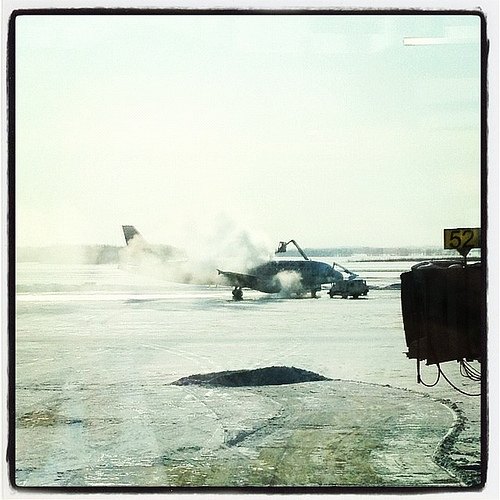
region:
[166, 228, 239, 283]
White smoke coming out of airplane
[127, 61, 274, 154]
Clear sunny blue day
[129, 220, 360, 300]
Airplane with white smoke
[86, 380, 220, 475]
Skid marks on pathway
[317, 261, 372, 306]
Truck close to airplane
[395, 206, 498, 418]
Equipment with 52 listed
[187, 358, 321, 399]
Gray dirt on pathway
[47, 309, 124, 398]
Gray pathway for airplanes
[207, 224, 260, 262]
White cloud of smoke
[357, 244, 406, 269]
Landscape background of trees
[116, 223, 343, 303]
an airplane parked on a runway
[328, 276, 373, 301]
a vehicle in front ofthe airplane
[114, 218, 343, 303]
an airplane mostly obscured by smoke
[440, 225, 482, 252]
a yellow sign with a number on it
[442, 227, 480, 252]
the number 52 in black letters on a yellow background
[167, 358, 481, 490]
a set of tire tracks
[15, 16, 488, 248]
an overcast sky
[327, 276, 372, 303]
emergency vehicles near the airplane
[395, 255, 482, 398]
partially extended passenger walkway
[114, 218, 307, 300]
a cloud of smoke by the airplane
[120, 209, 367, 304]
The partially hidden aircraft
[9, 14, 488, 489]
A misty day in open grounds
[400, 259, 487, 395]
The protruding piece of luggage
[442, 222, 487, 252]
The number sign on the right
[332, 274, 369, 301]
The gray vehicle by the plane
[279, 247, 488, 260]
Gray hills in the horizon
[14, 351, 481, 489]
The partly disturbed dirt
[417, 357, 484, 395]
The dark hanging straps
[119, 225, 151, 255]
The partially blocked plane tail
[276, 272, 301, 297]
The thick smoky area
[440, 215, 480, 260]
the number fifty two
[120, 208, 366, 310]
a smoking airplane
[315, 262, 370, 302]
a bucket truck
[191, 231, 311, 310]
a bucket truck over a plane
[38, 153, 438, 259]
a hazy skyline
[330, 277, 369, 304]
a white van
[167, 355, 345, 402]
A pile of ash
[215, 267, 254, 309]
landing gear for the plane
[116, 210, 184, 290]
tail wing hidden behind smoke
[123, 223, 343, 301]
airplane on the runway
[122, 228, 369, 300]
airplane being de-iced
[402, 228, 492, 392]
airport gate number 52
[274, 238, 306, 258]
de-icing crane above the airplane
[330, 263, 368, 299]
de-icing truck on the front of the plane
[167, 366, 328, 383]
small pile of show that has been plowed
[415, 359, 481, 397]
cables underneath the gate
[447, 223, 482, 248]
yellow gate number sign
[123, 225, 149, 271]
tail of the airplane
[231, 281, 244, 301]
rear landing gear of airplane